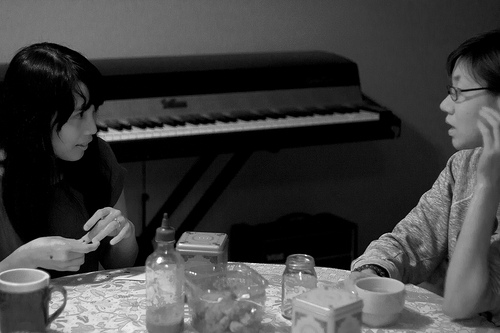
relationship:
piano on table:
[67, 35, 399, 167] [70, 107, 446, 248]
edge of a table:
[97, 254, 361, 281] [45, 270, 465, 330]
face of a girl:
[38, 83, 100, 163] [2, 17, 172, 302]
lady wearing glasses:
[340, 30, 499, 320] [443, 82, 498, 100]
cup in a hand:
[348, 267, 409, 332] [332, 255, 394, 302]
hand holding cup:
[332, 255, 394, 302] [348, 267, 409, 332]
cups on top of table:
[128, 222, 418, 325] [35, 227, 485, 331]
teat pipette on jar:
[155, 213, 175, 241] [145, 212, 185, 332]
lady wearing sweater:
[340, 30, 499, 320] [351, 147, 499, 326]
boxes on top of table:
[141, 217, 292, 295] [0, 250, 499, 331]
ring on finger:
[113, 214, 123, 227] [89, 217, 123, 247]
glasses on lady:
[444, 85, 497, 102] [340, 30, 499, 320]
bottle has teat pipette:
[144, 238, 185, 329] [156, 211, 172, 236]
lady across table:
[340, 30, 499, 320] [46, 259, 496, 331]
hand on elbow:
[466, 104, 497, 156] [441, 262, 489, 332]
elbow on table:
[441, 262, 489, 332] [228, 248, 347, 325]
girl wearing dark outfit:
[0, 41, 137, 279] [2, 132, 121, 277]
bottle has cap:
[144, 212, 186, 333] [155, 212, 172, 239]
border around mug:
[4, 260, 51, 291] [5, 263, 72, 325]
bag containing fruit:
[183, 260, 270, 331] [195, 299, 260, 331]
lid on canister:
[285, 250, 313, 275] [277, 250, 331, 302]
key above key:
[167, 115, 179, 130] [271, 111, 284, 131]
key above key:
[96, 104, 378, 142] [271, 111, 284, 131]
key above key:
[167, 115, 179, 130] [342, 106, 352, 126]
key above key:
[96, 104, 378, 142] [342, 106, 352, 126]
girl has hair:
[0, 41, 137, 279] [4, 40, 83, 170]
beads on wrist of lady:
[355, 264, 385, 276] [340, 30, 499, 320]